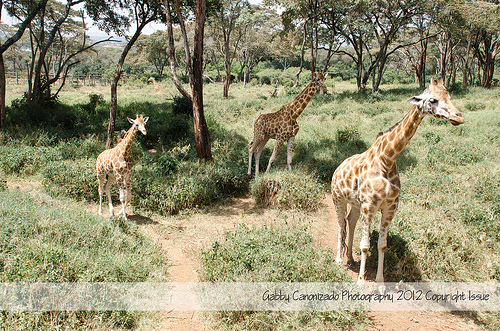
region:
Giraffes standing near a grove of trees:
[93, 77, 474, 277]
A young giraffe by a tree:
[80, 106, 167, 212]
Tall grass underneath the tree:
[140, 152, 214, 202]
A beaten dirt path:
[147, 229, 199, 314]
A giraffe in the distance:
[147, 77, 167, 102]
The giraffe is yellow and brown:
[309, 132, 434, 278]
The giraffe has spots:
[255, 110, 325, 163]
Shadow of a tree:
[22, 101, 84, 140]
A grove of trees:
[343, 11, 483, 75]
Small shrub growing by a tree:
[167, 91, 192, 117]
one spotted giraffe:
[79, 102, 172, 228]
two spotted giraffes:
[237, 53, 454, 324]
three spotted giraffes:
[61, 47, 486, 297]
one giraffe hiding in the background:
[132, 65, 179, 100]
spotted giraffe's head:
[129, 104, 166, 149]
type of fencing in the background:
[8, 61, 129, 93]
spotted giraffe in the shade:
[221, 62, 344, 187]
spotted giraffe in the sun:
[299, 76, 453, 303]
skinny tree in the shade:
[72, 3, 180, 153]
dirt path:
[123, 217, 196, 320]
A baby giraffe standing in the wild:
[75, 96, 164, 223]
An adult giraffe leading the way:
[328, 67, 465, 283]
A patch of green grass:
[191, 212, 338, 329]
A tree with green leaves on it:
[154, 2, 236, 164]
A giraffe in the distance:
[133, 65, 168, 107]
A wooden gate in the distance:
[2, 66, 124, 87]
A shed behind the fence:
[1, 26, 106, 72]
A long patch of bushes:
[146, 53, 356, 85]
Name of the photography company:
[210, 284, 499, 319]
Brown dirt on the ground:
[144, 212, 201, 325]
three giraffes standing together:
[67, 54, 465, 274]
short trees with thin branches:
[284, 2, 494, 90]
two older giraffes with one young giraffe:
[87, 82, 455, 296]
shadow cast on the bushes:
[11, 83, 202, 159]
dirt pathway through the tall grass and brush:
[42, 179, 349, 326]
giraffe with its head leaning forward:
[329, 91, 464, 291]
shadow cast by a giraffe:
[357, 225, 472, 321]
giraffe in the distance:
[142, 73, 172, 110]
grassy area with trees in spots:
[5, 11, 497, 316]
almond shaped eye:
[426, 96, 440, 106]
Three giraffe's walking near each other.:
[96, 60, 472, 270]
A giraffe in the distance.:
[123, 66, 190, 106]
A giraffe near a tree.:
[177, 97, 296, 163]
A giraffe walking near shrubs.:
[237, 199, 382, 309]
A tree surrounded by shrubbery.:
[150, 88, 242, 208]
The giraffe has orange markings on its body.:
[347, 160, 392, 201]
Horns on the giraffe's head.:
[417, 70, 448, 105]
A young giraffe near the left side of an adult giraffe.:
[80, 60, 380, 215]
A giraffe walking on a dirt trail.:
[295, 190, 425, 320]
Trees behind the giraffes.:
[240, 41, 465, 92]